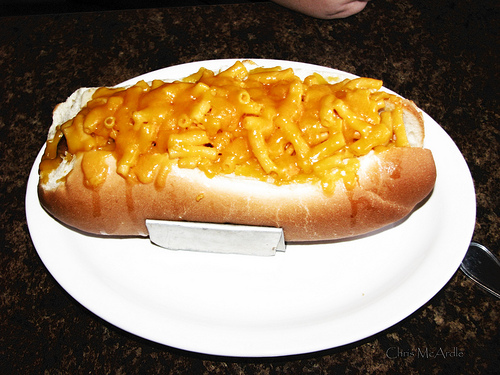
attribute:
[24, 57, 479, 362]
plate — white, round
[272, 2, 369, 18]
part of hand — showing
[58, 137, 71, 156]
hotdog — covered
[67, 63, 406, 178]
mac & cheese — yellow, orange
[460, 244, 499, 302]
silverware — metal, sliver, showing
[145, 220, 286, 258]
holder — white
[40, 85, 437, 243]
bun — brown, white, showing, toasted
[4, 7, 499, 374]
table — showing, dark, black